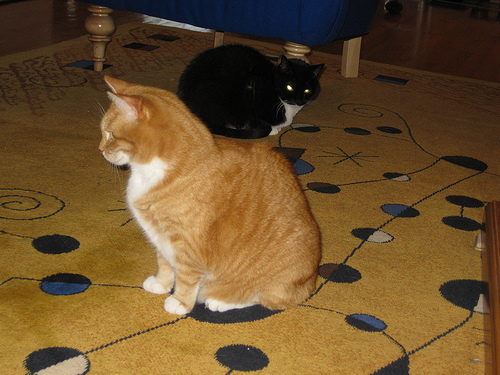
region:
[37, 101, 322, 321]
cat on the floor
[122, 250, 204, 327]
front paws of cat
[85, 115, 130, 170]
face of the cat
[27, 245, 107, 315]
round design on ground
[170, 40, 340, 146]
black and white cat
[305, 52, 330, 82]
ear of the cat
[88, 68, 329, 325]
tan cat sitting on rug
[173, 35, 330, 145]
black cat sitting on rug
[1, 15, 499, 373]
tan carpet with blue circle design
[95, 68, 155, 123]
two cat ears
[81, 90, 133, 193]
white cat whiskers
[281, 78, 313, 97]
two cat eyes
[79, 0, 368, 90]
legs of wooden table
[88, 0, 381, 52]
blue tablecloth on table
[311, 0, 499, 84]
brown hardwood floors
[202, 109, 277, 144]
black cat tail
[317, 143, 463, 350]
spots on the carpet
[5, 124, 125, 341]
the carpet is orange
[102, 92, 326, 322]
the cat is orange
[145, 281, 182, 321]
the paw is white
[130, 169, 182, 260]
the cat chest is white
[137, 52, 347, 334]
black cat behind the orange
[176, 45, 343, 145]
the cat is in a ball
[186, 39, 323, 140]
black cat on the floor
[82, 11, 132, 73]
wooden leg on the chair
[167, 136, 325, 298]
the cat is striped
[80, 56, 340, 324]
cat is color brown and white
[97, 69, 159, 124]
the ears of cat are pointy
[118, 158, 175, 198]
front neck is white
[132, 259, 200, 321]
paws of cat are white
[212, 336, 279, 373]
a blue round on the floor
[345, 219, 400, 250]
circle is blue and white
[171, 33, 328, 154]
eyes of cat are shiny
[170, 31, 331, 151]
cat is color black and white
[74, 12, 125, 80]
a leg of furniture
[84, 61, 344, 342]
cat facing to the left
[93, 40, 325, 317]
black and white cat behind brown and white cat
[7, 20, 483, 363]
tan carpeting with black lines connecting circles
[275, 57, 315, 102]
glowing yellow cat eyes on black head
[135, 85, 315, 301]
darker stripes on brown fur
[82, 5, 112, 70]
rings and curves on furniture leg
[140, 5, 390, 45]
bottom ege of blue and black furniture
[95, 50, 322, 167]
cats facing different directions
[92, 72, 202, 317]
cat sitting up on front legs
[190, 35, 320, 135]
legs tucked under and tail curled around body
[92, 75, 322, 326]
cat seated on black circle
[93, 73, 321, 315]
orange and white tabby cat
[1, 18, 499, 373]
tan rug with black and blue markings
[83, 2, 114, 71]
decorative wooden chair leg